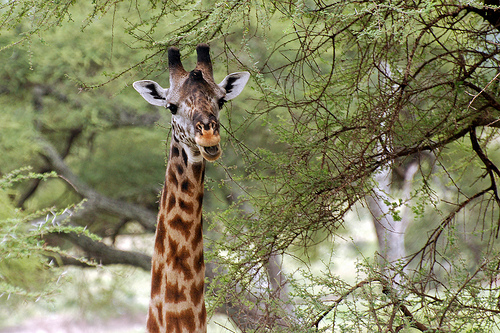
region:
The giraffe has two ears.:
[113, 36, 261, 331]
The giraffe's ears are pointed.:
[107, 26, 261, 330]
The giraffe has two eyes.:
[117, 32, 259, 169]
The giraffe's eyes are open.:
[120, 27, 260, 162]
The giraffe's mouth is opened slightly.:
[123, 27, 262, 171]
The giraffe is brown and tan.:
[120, 37, 257, 331]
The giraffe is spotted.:
[100, 24, 264, 330]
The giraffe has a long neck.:
[115, 17, 256, 328]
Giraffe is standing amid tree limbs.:
[21, 6, 496, 329]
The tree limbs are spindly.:
[247, 9, 497, 331]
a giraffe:
[93, 75, 263, 328]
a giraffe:
[129, 105, 225, 269]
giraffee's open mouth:
[190, 129, 247, 168]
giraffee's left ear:
[224, 73, 251, 113]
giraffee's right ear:
[113, 55, 191, 135]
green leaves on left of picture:
[2, 171, 88, 278]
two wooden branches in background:
[46, 153, 128, 275]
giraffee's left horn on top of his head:
[191, 34, 216, 71]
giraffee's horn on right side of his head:
[150, 28, 185, 81]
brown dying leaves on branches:
[338, 76, 428, 167]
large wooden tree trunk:
[338, 120, 439, 293]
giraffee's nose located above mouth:
[190, 114, 231, 138]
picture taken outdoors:
[49, 37, 459, 325]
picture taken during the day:
[52, 88, 499, 313]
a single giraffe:
[107, 52, 267, 326]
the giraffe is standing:
[140, 45, 221, 325]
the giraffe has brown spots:
[127, 66, 213, 328]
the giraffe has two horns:
[91, 25, 311, 222]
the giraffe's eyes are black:
[126, 66, 320, 158]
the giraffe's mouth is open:
[131, 102, 285, 197]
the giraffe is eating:
[140, 99, 324, 226]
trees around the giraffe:
[75, 39, 497, 289]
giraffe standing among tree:
[117, 31, 224, 325]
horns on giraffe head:
[161, 41, 211, 78]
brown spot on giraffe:
[171, 192, 193, 213]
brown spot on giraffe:
[175, 255, 192, 280]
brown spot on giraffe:
[179, 307, 193, 328]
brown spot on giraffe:
[156, 280, 185, 306]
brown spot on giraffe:
[143, 312, 158, 329]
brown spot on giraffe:
[193, 252, 205, 272]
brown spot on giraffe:
[152, 219, 167, 251]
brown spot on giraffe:
[188, 284, 205, 305]